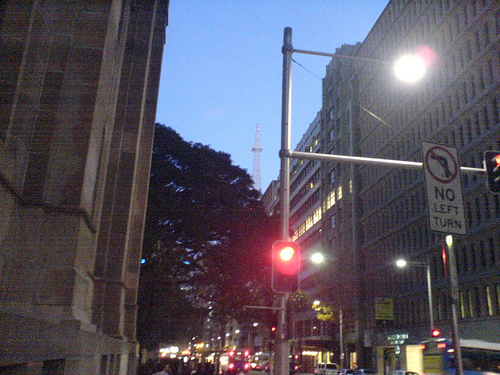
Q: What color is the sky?
A: Blue.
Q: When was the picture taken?
A: Dusk.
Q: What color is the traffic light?
A: Red.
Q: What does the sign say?
A: No left turn.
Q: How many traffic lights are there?
A: One.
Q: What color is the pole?
A: Silver.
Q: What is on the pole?
A: The traffic light.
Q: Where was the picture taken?
A: On the street.